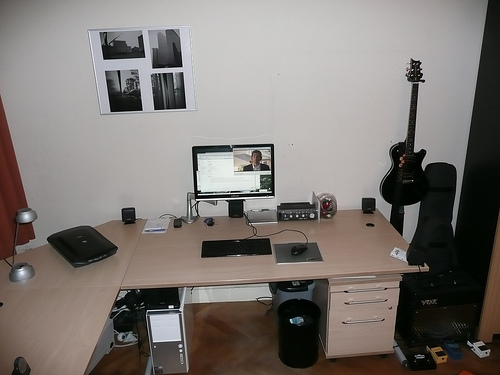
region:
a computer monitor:
[188, 140, 280, 207]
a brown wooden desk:
[1, 195, 430, 373]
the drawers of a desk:
[321, 273, 405, 363]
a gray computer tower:
[143, 284, 200, 374]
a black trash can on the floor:
[273, 288, 325, 371]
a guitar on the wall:
[368, 53, 434, 211]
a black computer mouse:
[286, 238, 313, 261]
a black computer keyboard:
[194, 231, 276, 266]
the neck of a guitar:
[402, 82, 424, 157]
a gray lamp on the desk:
[4, 203, 42, 292]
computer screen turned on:
[193, 142, 279, 205]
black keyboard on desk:
[204, 233, 270, 257]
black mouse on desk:
[291, 239, 306, 259]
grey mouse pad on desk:
[276, 234, 328, 273]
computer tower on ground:
[148, 293, 193, 373]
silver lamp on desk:
[10, 200, 37, 288]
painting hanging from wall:
[94, 12, 191, 117]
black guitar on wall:
[374, 59, 434, 199]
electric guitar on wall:
[377, 55, 433, 205]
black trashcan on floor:
[274, 292, 324, 368]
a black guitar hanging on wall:
[378, 52, 428, 207]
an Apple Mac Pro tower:
[145, 290, 190, 372]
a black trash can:
[275, 296, 320, 366]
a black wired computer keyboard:
[197, 235, 267, 255]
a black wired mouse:
[285, 241, 305, 256]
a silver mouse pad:
[273, 240, 321, 266]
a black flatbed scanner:
[44, 223, 118, 266]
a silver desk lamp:
[6, 207, 37, 282]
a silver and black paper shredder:
[269, 280, 311, 319]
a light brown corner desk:
[1, 216, 427, 373]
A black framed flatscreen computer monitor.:
[189, 139, 277, 200]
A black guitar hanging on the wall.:
[379, 59, 431, 204]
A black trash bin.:
[280, 299, 320, 367]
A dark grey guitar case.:
[410, 162, 460, 274]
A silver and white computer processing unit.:
[143, 289, 195, 372]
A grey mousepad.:
[274, 238, 325, 262]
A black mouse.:
[287, 244, 312, 254]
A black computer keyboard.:
[202, 234, 272, 257]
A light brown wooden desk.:
[4, 214, 434, 373]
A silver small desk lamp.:
[4, 208, 46, 283]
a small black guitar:
[380, 42, 430, 207]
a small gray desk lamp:
[5, 205, 42, 283]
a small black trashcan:
[269, 295, 329, 368]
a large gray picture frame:
[84, 21, 206, 121]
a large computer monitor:
[186, 140, 289, 202]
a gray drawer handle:
[346, 296, 395, 306]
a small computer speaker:
[120, 205, 139, 225]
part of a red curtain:
[0, 104, 43, 259]